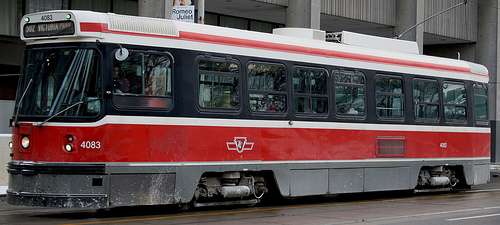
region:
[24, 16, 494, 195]
A black grey and white bus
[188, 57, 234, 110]
A clear glass bus window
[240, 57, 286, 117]
A clear glass bus window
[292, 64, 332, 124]
A clear glass bus window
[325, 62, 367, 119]
A clear glass bus window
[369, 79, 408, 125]
A clear glass bus window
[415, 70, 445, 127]
A clear glass bus window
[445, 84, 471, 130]
A clear glass bus window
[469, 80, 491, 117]
A clear glass bus window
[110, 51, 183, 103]
A clear glass bus window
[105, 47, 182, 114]
the window on a train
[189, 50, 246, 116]
the window of a train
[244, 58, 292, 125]
the window of a train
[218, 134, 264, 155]
a train company logo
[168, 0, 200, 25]
a poster for romeo and juliet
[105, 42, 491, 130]
a row of windows on a train car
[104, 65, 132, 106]
the conductor of a train car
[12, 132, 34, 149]
the headlight of a train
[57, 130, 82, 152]
the headlight of a train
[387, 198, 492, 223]
a wet street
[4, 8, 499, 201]
a bus on the road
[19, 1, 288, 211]
a bus on the street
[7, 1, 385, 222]
a trolly on the road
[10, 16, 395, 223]
a trolly on the street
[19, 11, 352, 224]
an electrical trolly on the road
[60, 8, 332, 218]
an electrical trolly on road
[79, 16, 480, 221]
a passenger bus on the road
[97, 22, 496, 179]
a passenger bus on the street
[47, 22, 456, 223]
a street with a bus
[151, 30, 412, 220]
a road with bus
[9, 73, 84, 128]
windshield wipers on a tram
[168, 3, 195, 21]
white "Romeo Juliet" sign above a tram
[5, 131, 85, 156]
headlights on a tram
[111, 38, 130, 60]
driver's side view mirror on a tram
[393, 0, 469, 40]
metal pole to connect a tram to power lines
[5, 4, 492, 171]
red and white tram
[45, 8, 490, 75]
white roof on a tram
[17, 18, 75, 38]
sign displaying tram's final destination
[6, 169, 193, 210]
dirt on a tram's bumper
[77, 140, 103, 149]
white tram number on a red background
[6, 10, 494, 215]
red and white bus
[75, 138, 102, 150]
white number print on a bus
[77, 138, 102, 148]
white number print reading 4083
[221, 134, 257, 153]
white design on a bus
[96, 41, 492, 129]
windows on a bus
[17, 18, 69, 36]
white text print on a bus sign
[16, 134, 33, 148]
round white bus light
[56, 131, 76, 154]
two bus lights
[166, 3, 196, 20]
black and white sign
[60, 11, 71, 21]
green light on a bus